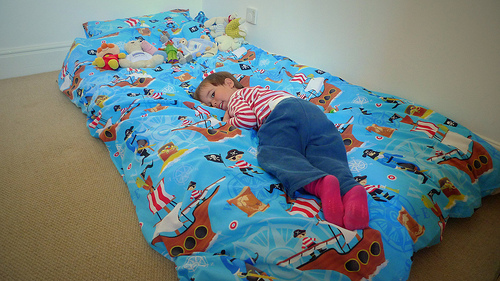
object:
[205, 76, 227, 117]
eyes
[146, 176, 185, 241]
sail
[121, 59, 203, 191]
pattern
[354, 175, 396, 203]
pirate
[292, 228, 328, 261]
pirate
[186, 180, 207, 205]
pirate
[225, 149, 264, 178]
pirate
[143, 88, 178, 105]
pirate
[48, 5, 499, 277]
comforter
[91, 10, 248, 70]
stuffed animals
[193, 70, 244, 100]
hair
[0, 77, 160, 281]
carpet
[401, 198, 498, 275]
carpet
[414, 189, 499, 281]
floor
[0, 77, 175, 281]
floor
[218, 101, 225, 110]
mouth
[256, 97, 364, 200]
pants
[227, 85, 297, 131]
shirt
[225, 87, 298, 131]
pajamas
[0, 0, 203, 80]
wall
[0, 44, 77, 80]
baseboard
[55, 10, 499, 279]
bed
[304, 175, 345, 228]
sock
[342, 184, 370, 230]
sock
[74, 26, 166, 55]
pillow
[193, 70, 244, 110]
head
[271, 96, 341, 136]
butt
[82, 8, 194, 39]
pillow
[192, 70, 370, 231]
boy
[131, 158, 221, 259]
boat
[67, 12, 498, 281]
pirate design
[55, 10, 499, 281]
cover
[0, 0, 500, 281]
bedroom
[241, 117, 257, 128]
elbow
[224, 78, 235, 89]
ear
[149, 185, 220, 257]
design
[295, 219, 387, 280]
pirate ship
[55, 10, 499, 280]
bed cover